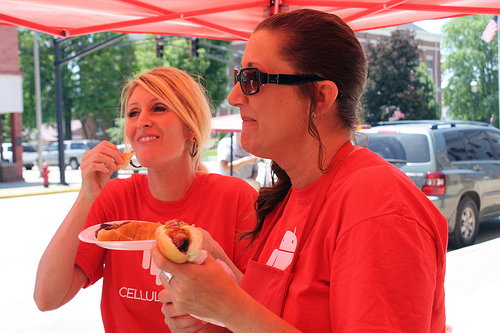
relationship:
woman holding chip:
[31, 65, 260, 333] [113, 144, 133, 169]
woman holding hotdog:
[150, 8, 447, 332] [135, 197, 212, 273]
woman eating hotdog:
[150, 8, 447, 332] [154, 216, 204, 263]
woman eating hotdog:
[31, 65, 260, 333] [94, 216, 160, 242]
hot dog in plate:
[65, 207, 151, 259] [61, 232, 134, 267]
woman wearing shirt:
[150, 8, 447, 332] [225, 146, 448, 332]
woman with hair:
[82, 58, 232, 330] [119, 66, 210, 176]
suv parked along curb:
[356, 117, 498, 245] [446, 237, 498, 331]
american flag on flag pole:
[476, 6, 498, 48] [496, 12, 498, 64]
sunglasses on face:
[233, 66, 324, 93] [226, 27, 308, 151]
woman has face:
[150, 8, 447, 332] [226, 27, 308, 151]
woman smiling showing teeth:
[31, 65, 260, 333] [133, 131, 160, 144]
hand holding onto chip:
[93, 138, 126, 168] [117, 151, 137, 169]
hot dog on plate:
[94, 220, 162, 242] [96, 223, 142, 253]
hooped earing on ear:
[186, 134, 200, 158] [185, 127, 197, 144]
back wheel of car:
[448, 194, 480, 249] [352, 120, 499, 246]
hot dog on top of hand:
[147, 216, 227, 268] [148, 265, 286, 331]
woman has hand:
[185, 14, 429, 330] [148, 265, 286, 331]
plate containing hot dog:
[69, 210, 169, 265] [93, 218, 166, 247]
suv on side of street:
[350, 119, 499, 250] [445, 227, 499, 257]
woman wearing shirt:
[150, 8, 447, 332] [224, 138, 449, 331]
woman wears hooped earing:
[150, 8, 447, 332] [186, 136, 200, 158]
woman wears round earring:
[150, 8, 447, 332] [110, 145, 146, 175]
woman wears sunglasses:
[150, 8, 447, 332] [227, 65, 324, 95]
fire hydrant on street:
[35, 170, 68, 202] [25, 160, 214, 274]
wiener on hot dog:
[167, 222, 187, 249] [154, 217, 206, 264]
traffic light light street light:
[156, 33, 164, 58] [190, 35, 199, 59]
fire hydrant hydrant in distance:
[40, 161, 49, 187] [15, 112, 57, 223]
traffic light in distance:
[149, 41, 165, 55] [21, 51, 99, 181]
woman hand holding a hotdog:
[31, 65, 260, 333] [154, 220, 202, 262]